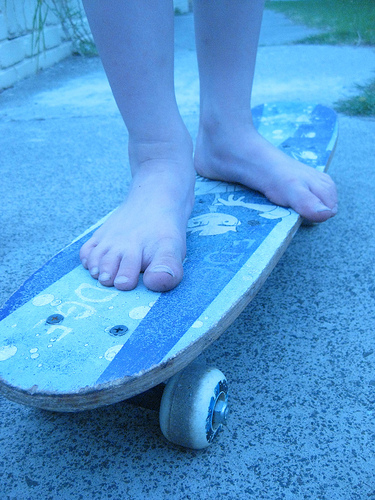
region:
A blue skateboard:
[11, 112, 337, 383]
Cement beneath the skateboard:
[250, 340, 336, 463]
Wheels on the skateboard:
[152, 363, 244, 454]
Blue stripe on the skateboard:
[93, 306, 205, 378]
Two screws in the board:
[47, 303, 137, 346]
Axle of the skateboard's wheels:
[93, 381, 211, 439]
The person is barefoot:
[71, 93, 342, 275]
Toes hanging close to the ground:
[292, 161, 342, 224]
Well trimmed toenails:
[86, 268, 135, 288]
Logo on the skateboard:
[185, 191, 241, 241]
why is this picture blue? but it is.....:
[1, 0, 374, 499]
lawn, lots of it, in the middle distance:
[263, 0, 374, 142]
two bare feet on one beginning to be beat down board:
[0, 0, 345, 421]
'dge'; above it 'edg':
[25, 264, 128, 348]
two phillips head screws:
[40, 307, 130, 340]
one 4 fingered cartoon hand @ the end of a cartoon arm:
[206, 190, 287, 223]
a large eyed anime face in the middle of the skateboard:
[178, 197, 246, 242]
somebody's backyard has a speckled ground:
[1, 115, 372, 495]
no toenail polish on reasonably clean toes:
[63, 189, 341, 300]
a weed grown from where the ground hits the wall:
[12, 0, 107, 80]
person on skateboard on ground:
[4, 87, 354, 457]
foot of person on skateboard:
[76, 150, 191, 293]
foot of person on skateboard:
[195, 128, 354, 221]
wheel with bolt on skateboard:
[169, 376, 232, 468]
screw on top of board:
[107, 320, 138, 346]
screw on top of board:
[39, 313, 71, 339]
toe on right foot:
[137, 261, 175, 290]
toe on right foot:
[113, 267, 144, 291]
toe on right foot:
[95, 268, 110, 283]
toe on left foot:
[288, 199, 327, 224]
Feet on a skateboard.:
[15, 99, 351, 327]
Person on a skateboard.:
[180, 193, 292, 243]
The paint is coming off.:
[46, 356, 185, 399]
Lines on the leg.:
[121, 130, 187, 172]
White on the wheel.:
[194, 378, 220, 452]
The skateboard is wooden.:
[21, 265, 291, 402]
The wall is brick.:
[8, 8, 80, 73]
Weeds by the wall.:
[36, 3, 106, 70]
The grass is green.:
[291, 0, 370, 40]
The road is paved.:
[253, 375, 350, 497]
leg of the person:
[64, 166, 218, 293]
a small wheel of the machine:
[174, 365, 249, 457]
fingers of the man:
[73, 236, 199, 305]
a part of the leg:
[67, 4, 374, 264]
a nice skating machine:
[1, 219, 280, 498]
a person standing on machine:
[70, 4, 340, 470]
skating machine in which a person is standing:
[29, 2, 331, 448]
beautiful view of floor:
[269, 282, 372, 488]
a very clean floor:
[15, 287, 364, 497]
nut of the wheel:
[214, 401, 235, 427]